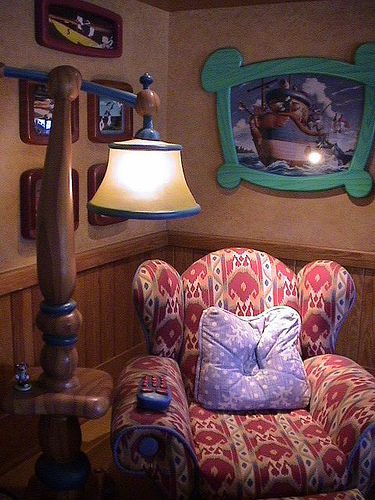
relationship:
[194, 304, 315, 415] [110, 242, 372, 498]
purple pillow on chair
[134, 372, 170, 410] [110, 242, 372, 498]
remote control on chair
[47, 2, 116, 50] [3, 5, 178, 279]
picture near wall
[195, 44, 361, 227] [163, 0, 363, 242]
picture on wall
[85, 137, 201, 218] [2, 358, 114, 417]
lampshade on table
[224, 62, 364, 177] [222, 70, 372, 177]
boat in picture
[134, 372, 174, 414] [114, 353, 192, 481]
remote control on chair arm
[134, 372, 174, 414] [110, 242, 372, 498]
remote control on chair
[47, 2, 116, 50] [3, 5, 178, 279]
picture on wall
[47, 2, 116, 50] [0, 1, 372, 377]
picture on wall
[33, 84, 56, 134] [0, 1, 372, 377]
picture on wall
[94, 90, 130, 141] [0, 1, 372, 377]
picture on wall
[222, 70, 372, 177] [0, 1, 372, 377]
picture on wall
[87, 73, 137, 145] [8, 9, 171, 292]
picture on wall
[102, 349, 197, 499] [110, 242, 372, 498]
arm of chair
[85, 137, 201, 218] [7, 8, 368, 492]
lampshade in room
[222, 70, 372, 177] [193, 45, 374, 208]
picture has aqua frame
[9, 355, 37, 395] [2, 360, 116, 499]
figurine on table